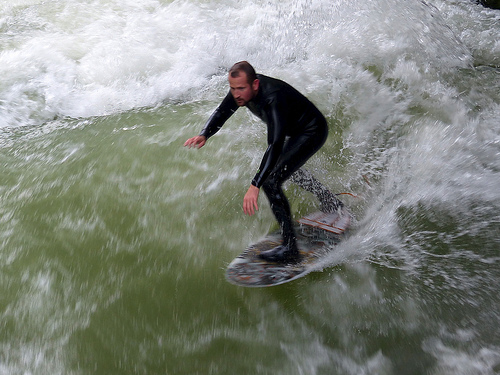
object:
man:
[188, 56, 334, 262]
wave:
[82, 29, 180, 69]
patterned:
[304, 215, 343, 235]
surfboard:
[226, 171, 400, 289]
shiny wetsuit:
[201, 76, 347, 261]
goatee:
[237, 101, 244, 106]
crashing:
[12, 8, 499, 123]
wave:
[328, 51, 449, 186]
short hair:
[228, 60, 259, 80]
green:
[0, 113, 253, 375]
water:
[3, 0, 493, 121]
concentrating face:
[229, 77, 254, 106]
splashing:
[374, 111, 469, 234]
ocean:
[0, 12, 498, 374]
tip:
[216, 263, 264, 291]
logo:
[297, 225, 319, 238]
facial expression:
[228, 70, 248, 108]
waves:
[262, 20, 339, 55]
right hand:
[183, 134, 207, 150]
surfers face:
[226, 71, 255, 106]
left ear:
[253, 78, 260, 91]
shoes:
[258, 241, 300, 263]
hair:
[229, 60, 261, 85]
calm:
[2, 115, 262, 375]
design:
[253, 230, 318, 273]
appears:
[9, 10, 488, 106]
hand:
[241, 186, 260, 216]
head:
[226, 60, 261, 107]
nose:
[233, 88, 240, 98]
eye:
[237, 87, 245, 90]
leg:
[260, 137, 327, 245]